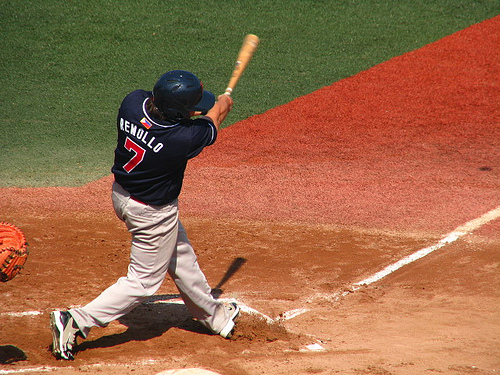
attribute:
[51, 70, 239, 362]
batter — swinging, playing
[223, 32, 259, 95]
bat — wooden, brown, wood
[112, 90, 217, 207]
jersey — dark blue, blue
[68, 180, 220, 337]
pants — gray, white, light tan, tan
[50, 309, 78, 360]
shoe — black, white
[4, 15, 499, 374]
sand — red, orange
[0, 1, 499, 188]
grass — green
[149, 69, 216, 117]
helmet — navy blue, blue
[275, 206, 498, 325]
line — white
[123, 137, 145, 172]
number 7 — red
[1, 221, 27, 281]
glove — brown, light brown